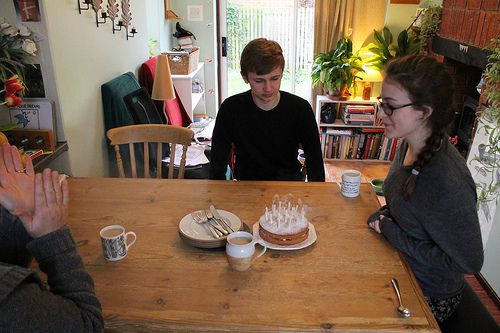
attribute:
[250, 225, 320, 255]
plate — white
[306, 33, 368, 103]
plant — green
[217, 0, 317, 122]
door — sliding 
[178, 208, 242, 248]
plates — stacked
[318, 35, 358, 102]
plant — healthy, potted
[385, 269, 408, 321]
spoon — silver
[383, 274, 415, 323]
spoon — silver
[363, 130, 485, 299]
shirt — gray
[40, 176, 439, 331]
table — brown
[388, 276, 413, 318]
spoon — silver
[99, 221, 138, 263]
cup — full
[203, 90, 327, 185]
top — black